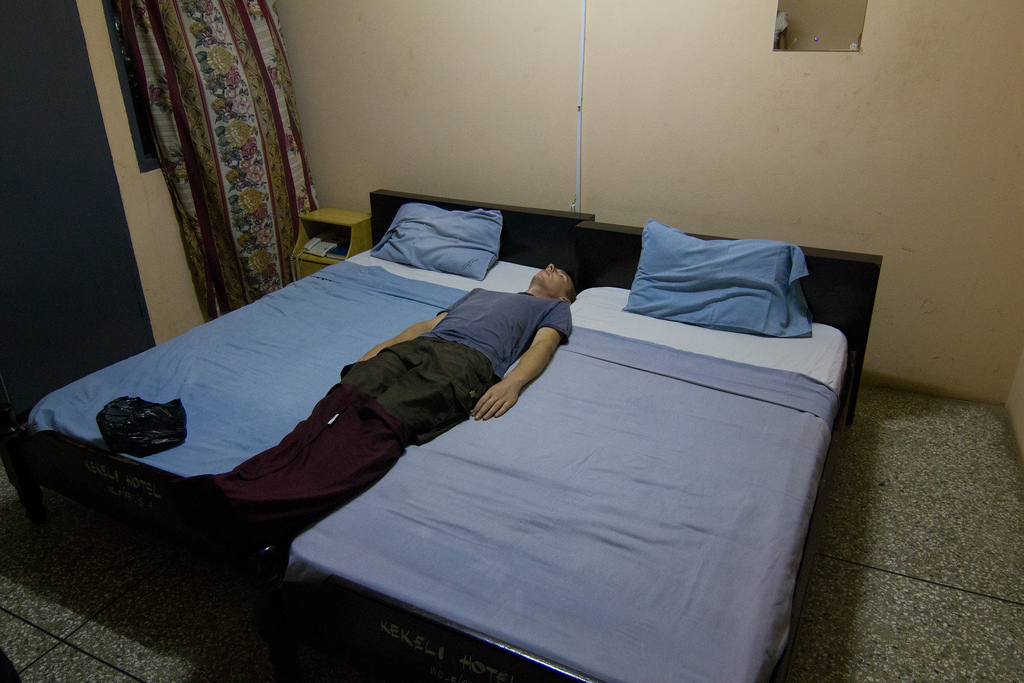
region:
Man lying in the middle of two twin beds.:
[47, 150, 882, 678]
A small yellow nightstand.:
[287, 199, 364, 288]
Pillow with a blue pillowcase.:
[622, 213, 812, 344]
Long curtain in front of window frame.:
[111, 5, 301, 319]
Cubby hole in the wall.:
[756, 0, 889, 83]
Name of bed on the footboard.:
[7, 422, 251, 587]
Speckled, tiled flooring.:
[801, 393, 1011, 679]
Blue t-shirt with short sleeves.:
[433, 284, 574, 360]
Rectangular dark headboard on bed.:
[573, 211, 884, 426]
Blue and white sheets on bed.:
[35, 238, 851, 646]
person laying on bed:
[155, 241, 588, 590]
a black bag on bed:
[95, 391, 216, 474]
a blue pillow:
[585, 205, 839, 336]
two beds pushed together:
[6, 168, 927, 680]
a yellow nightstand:
[281, 187, 373, 277]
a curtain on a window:
[87, 0, 359, 320]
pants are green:
[341, 323, 490, 444]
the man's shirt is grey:
[398, 256, 575, 378]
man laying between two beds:
[187, 241, 593, 596]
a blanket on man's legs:
[176, 373, 420, 528]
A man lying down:
[172, 257, 618, 570]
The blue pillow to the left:
[359, 184, 512, 277]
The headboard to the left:
[365, 184, 597, 287]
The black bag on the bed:
[90, 393, 201, 460]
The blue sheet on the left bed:
[30, 263, 458, 461]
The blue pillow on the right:
[615, 209, 835, 340]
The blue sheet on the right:
[381, 314, 841, 679]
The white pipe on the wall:
[543, 1, 626, 213]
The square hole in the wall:
[736, 3, 893, 74]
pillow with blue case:
[372, 196, 502, 277]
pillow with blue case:
[622, 220, 813, 339]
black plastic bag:
[94, 388, 187, 459]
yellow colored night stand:
[291, 205, 369, 276]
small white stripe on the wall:
[571, 6, 588, 213]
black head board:
[369, 186, 594, 285]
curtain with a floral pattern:
[120, 3, 323, 314]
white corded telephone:
[294, 239, 337, 278]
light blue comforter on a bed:
[21, 259, 465, 488]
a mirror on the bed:
[746, 7, 899, 115]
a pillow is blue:
[379, 167, 582, 355]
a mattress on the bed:
[499, 166, 835, 679]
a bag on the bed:
[63, 352, 270, 504]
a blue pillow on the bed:
[624, 205, 824, 360]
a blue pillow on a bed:
[368, 186, 504, 298]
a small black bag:
[96, 376, 207, 476]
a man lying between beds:
[184, 230, 593, 562]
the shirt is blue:
[438, 274, 571, 380]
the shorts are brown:
[311, 332, 488, 437]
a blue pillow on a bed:
[544, 231, 819, 368]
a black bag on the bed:
[68, 376, 227, 519]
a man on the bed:
[378, 239, 609, 392]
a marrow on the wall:
[724, 12, 877, 66]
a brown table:
[249, 157, 393, 336]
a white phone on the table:
[272, 217, 343, 290]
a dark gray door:
[27, 78, 95, 306]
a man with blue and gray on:
[139, 255, 601, 582]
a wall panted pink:
[461, 53, 759, 251]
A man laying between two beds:
[332, 203, 608, 520]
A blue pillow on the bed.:
[626, 219, 826, 356]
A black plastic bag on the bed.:
[75, 379, 209, 475]